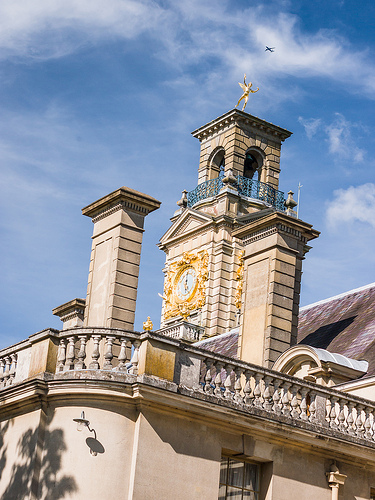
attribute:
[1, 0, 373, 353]
sky — blue, sunny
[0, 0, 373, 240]
clouds — white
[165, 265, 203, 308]
clock face — white 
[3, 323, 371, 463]
balcony — stone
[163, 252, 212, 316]
frame — gold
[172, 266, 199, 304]
clock face — white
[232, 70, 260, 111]
statue — green 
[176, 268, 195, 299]
numbers — black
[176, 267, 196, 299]
clock — white